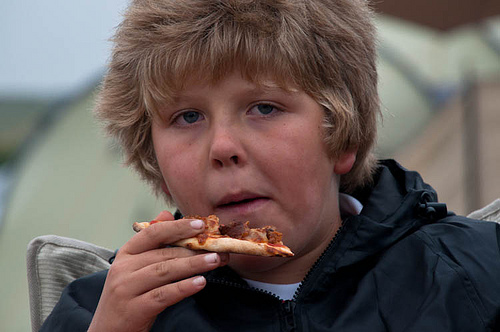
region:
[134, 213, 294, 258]
Crust of a piece of pizza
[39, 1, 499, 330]
Young boy eating pizza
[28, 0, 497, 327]
Boy wearing a black windbreaker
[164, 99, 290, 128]
Pair of blue eyes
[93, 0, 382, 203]
Short feathered blond hair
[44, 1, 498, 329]
Boy wearing a white shirt under a windbreaker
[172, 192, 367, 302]
Collar of a white shirt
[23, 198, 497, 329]
Gray fold up chair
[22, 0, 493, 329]
Boy sitting on a gray chair eating pizza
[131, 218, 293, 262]
baked pizza crust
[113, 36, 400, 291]
boy eating pizza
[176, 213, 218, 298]
boy's hand with dirty fingernails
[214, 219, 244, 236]
pepperoni on a mostly eaten pizza slice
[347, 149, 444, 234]
hood on a black jacket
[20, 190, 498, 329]
gray canvas folding chair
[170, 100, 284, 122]
boy with blue eyes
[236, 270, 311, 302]
white shirt collar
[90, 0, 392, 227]
boy with blonde hair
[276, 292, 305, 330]
zipper pull on a black jacket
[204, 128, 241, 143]
freckles on a boy's nose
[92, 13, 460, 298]
boy eating slice of pizza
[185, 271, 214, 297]
finger of the boy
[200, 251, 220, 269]
finger of the boy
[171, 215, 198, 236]
finger of the boy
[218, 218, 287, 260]
pizza in the hand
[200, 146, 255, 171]
nose of the boy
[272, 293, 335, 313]
zipper pull on jacket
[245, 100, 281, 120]
eye of the boy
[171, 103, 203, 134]
eye of the boy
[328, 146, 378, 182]
ear of the boy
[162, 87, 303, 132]
the eyes are blue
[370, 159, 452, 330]
the jacket is blue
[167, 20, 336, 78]
the hair is blonde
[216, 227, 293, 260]
the pizza is thin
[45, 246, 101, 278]
the chair is gray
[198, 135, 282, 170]
the boy has a nose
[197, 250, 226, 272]
the fingernail is dirty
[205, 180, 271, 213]
the boy has a mouth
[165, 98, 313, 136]
the boy has eyes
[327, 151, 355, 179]
the boy has an earlobe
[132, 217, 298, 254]
slice of pizza in the woman's hands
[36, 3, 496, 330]
woman eating a slice of pizza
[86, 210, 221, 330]
woman's right hand with polished nails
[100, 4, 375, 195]
short dark blond hair on the woman's head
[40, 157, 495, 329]
black jacket on the woman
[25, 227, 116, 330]
gray fabric chair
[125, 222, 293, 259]
crust of a pizza slice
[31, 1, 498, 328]
the woman is chewing a piece of pizza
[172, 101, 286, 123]
blue eyes on the woman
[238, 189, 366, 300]
white collar on the woman